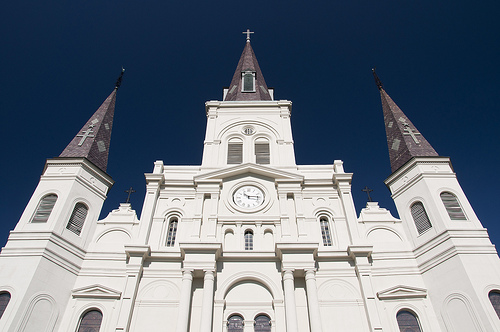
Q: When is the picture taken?
A: Daytime.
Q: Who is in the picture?
A: No one.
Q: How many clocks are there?
A: 1.